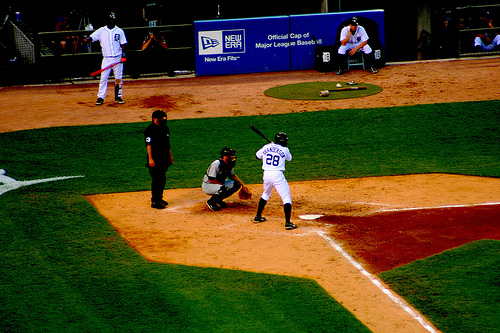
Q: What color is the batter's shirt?
A: Black.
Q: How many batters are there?
A: One.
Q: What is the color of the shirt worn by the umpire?
A: Black.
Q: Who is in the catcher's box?
A: Catcher.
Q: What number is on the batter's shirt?
A: 28.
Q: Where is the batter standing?
A: Batter's box.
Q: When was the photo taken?
A: Day time.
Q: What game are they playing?
A: Baseball.